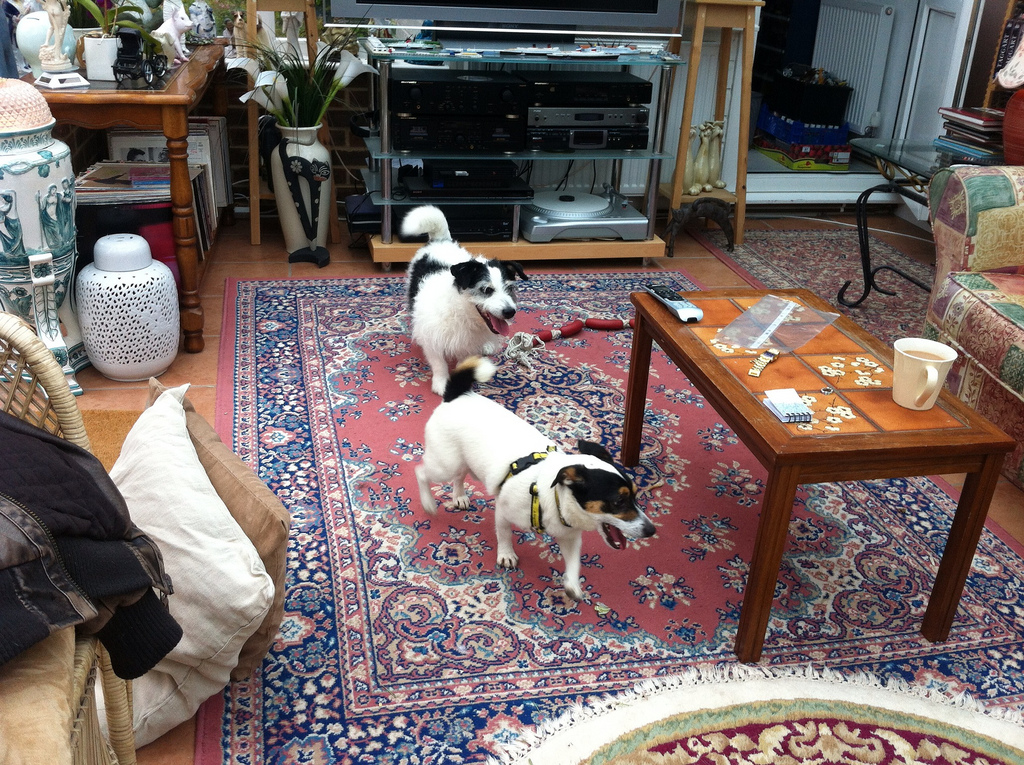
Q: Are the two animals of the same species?
A: Yes, all the animals are dogs.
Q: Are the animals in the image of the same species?
A: Yes, all the animals are dogs.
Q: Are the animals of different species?
A: No, all the animals are dogs.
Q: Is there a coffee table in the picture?
A: Yes, there is a coffee table.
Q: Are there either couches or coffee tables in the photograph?
A: Yes, there is a coffee table.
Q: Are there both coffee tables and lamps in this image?
A: No, there is a coffee table but no lamps.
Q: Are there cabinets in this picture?
A: No, there are no cabinets.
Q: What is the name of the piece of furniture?
A: The piece of furniture is a coffee table.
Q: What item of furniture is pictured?
A: The piece of furniture is a coffee table.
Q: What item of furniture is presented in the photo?
A: The piece of furniture is a coffee table.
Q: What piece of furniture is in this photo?
A: The piece of furniture is a coffee table.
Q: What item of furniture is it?
A: The piece of furniture is a coffee table.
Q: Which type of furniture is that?
A: That is a coffee table.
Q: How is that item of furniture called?
A: That is a coffee table.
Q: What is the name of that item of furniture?
A: That is a coffee table.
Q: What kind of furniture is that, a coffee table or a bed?
A: That is a coffee table.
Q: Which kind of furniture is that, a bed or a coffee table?
A: That is a coffee table.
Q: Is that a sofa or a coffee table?
A: That is a coffee table.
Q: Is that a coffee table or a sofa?
A: That is a coffee table.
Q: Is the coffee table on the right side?
A: Yes, the coffee table is on the right of the image.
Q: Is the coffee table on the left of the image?
A: No, the coffee table is on the right of the image.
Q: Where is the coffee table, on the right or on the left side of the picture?
A: The coffee table is on the right of the image.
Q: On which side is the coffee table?
A: The coffee table is on the right of the image.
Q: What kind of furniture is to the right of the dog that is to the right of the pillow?
A: The piece of furniture is a coffee table.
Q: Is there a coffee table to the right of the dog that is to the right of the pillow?
A: Yes, there is a coffee table to the right of the dog.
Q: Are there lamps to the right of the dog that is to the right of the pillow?
A: No, there is a coffee table to the right of the dog.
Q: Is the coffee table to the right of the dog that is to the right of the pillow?
A: Yes, the coffee table is to the right of the dog.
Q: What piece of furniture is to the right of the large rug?
A: The piece of furniture is a coffee table.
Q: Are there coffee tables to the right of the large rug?
A: Yes, there is a coffee table to the right of the rug.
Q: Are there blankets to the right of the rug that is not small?
A: No, there is a coffee table to the right of the rug.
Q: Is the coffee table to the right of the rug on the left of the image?
A: Yes, the coffee table is to the right of the rug.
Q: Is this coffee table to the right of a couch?
A: No, the coffee table is to the right of the rug.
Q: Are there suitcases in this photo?
A: No, there are no suitcases.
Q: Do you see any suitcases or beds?
A: No, there are no suitcases or beds.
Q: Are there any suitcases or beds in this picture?
A: No, there are no suitcases or beds.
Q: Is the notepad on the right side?
A: Yes, the notepad is on the right of the image.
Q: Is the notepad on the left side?
A: No, the notepad is on the right of the image.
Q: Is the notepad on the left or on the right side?
A: The notepad is on the right of the image.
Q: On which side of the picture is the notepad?
A: The notepad is on the right of the image.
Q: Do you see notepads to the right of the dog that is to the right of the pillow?
A: Yes, there is a notepad to the right of the dog.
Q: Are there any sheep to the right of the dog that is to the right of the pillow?
A: No, there is a notepad to the right of the dog.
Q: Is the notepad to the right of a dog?
A: Yes, the notepad is to the right of a dog.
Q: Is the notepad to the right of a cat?
A: No, the notepad is to the right of a dog.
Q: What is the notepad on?
A: The notepad is on the coffee table.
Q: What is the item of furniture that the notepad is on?
A: The piece of furniture is a coffee table.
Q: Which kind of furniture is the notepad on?
A: The notepad is on the coffee table.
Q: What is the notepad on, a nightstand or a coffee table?
A: The notepad is on a coffee table.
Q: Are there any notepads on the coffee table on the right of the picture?
A: Yes, there is a notepad on the coffee table.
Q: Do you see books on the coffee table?
A: No, there is a notepad on the coffee table.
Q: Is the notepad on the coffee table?
A: Yes, the notepad is on the coffee table.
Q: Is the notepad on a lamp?
A: No, the notepad is on the coffee table.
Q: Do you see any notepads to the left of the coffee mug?
A: Yes, there is a notepad to the left of the coffee mug.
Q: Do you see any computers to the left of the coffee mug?
A: No, there is a notepad to the left of the coffee mug.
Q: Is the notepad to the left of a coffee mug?
A: Yes, the notepad is to the left of a coffee mug.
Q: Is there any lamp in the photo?
A: No, there are no lamps.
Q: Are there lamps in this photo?
A: No, there are no lamps.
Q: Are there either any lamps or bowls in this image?
A: No, there are no lamps or bowls.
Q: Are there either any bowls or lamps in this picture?
A: No, there are no lamps or bowls.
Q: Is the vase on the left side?
A: Yes, the vase is on the left of the image.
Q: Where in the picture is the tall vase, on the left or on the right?
A: The vase is on the left of the image.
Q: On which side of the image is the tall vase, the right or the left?
A: The vase is on the left of the image.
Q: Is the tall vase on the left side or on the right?
A: The vase is on the left of the image.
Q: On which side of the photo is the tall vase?
A: The vase is on the left of the image.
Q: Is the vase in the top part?
A: Yes, the vase is in the top of the image.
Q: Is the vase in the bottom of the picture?
A: No, the vase is in the top of the image.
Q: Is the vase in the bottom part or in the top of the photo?
A: The vase is in the top of the image.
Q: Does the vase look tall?
A: Yes, the vase is tall.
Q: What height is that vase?
A: The vase is tall.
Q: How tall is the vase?
A: The vase is tall.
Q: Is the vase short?
A: No, the vase is tall.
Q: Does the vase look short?
A: No, the vase is tall.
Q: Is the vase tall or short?
A: The vase is tall.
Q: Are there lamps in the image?
A: No, there are no lamps.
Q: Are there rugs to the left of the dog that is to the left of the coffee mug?
A: Yes, there is a rug to the left of the dog.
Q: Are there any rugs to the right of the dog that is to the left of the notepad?
A: No, the rug is to the left of the dog.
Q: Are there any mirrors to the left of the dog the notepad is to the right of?
A: No, there is a rug to the left of the dog.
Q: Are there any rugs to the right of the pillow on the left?
A: Yes, there is a rug to the right of the pillow.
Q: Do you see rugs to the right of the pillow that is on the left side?
A: Yes, there is a rug to the right of the pillow.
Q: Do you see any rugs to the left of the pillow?
A: No, the rug is to the right of the pillow.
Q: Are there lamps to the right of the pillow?
A: No, there is a rug to the right of the pillow.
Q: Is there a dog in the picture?
A: Yes, there is a dog.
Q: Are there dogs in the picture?
A: Yes, there is a dog.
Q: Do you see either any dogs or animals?
A: Yes, there is a dog.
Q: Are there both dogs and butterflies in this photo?
A: No, there is a dog but no butterflies.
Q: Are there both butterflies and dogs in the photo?
A: No, there is a dog but no butterflies.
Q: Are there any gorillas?
A: No, there are no gorillas.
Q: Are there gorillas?
A: No, there are no gorillas.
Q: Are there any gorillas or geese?
A: No, there are no gorillas or geese.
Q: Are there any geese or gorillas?
A: No, there are no gorillas or geese.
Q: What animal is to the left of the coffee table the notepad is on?
A: The animal is a dog.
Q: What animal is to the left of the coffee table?
A: The animal is a dog.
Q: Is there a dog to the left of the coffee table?
A: Yes, there is a dog to the left of the coffee table.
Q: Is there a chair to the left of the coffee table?
A: No, there is a dog to the left of the coffee table.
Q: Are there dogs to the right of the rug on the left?
A: Yes, there is a dog to the right of the rug.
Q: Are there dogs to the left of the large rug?
A: No, the dog is to the right of the rug.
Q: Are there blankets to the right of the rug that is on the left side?
A: No, there is a dog to the right of the rug.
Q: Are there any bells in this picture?
A: No, there are no bells.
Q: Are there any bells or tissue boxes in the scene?
A: No, there are no bells or tissue boxes.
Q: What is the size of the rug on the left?
A: The rug is large.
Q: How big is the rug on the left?
A: The rug is large.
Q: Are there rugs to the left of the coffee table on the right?
A: Yes, there is a rug to the left of the coffee table.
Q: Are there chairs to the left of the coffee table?
A: No, there is a rug to the left of the coffee table.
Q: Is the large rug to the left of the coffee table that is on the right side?
A: Yes, the rug is to the left of the coffee table.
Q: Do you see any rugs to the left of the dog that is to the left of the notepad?
A: Yes, there is a rug to the left of the dog.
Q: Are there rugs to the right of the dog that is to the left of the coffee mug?
A: No, the rug is to the left of the dog.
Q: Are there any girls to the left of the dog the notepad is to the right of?
A: No, there is a rug to the left of the dog.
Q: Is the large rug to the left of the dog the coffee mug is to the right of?
A: Yes, the rug is to the left of the dog.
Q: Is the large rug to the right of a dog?
A: No, the rug is to the left of a dog.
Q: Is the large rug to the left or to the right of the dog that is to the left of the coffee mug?
A: The rug is to the left of the dog.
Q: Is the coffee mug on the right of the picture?
A: Yes, the coffee mug is on the right of the image.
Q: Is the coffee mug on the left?
A: No, the coffee mug is on the right of the image.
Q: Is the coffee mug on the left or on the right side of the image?
A: The coffee mug is on the right of the image.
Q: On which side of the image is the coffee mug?
A: The coffee mug is on the right of the image.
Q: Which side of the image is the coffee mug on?
A: The coffee mug is on the right of the image.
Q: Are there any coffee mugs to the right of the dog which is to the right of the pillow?
A: Yes, there is a coffee mug to the right of the dog.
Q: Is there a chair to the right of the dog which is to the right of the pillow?
A: No, there is a coffee mug to the right of the dog.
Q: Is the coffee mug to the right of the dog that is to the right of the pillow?
A: Yes, the coffee mug is to the right of the dog.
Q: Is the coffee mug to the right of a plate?
A: No, the coffee mug is to the right of the dog.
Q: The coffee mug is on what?
A: The coffee mug is on the coffee table.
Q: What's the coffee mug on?
A: The coffee mug is on the coffee table.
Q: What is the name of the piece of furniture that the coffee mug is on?
A: The piece of furniture is a coffee table.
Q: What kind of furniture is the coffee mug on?
A: The coffee mug is on the coffee table.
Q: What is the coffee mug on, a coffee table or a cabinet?
A: The coffee mug is on a coffee table.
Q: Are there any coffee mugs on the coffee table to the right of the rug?
A: Yes, there is a coffee mug on the coffee table.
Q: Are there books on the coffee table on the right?
A: No, there is a coffee mug on the coffee table.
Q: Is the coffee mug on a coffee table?
A: Yes, the coffee mug is on a coffee table.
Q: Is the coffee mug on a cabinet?
A: No, the coffee mug is on a coffee table.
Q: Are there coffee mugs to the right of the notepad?
A: Yes, there is a coffee mug to the right of the notepad.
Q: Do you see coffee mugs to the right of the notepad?
A: Yes, there is a coffee mug to the right of the notepad.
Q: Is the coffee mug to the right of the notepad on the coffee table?
A: Yes, the coffee mug is to the right of the notepad.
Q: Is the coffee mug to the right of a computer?
A: No, the coffee mug is to the right of the notepad.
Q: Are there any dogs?
A: Yes, there is a dog.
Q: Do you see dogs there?
A: Yes, there is a dog.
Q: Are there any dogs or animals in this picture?
A: Yes, there is a dog.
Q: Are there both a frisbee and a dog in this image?
A: No, there is a dog but no frisbees.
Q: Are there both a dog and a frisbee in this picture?
A: No, there is a dog but no frisbees.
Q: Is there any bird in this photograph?
A: No, there are no birds.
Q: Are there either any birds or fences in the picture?
A: No, there are no birds or fences.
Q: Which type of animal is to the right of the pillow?
A: The animal is a dog.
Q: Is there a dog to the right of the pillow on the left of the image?
A: Yes, there is a dog to the right of the pillow.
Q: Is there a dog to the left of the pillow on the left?
A: No, the dog is to the right of the pillow.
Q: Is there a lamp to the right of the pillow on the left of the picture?
A: No, there is a dog to the right of the pillow.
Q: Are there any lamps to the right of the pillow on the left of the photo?
A: No, there is a dog to the right of the pillow.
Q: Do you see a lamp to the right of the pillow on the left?
A: No, there is a dog to the right of the pillow.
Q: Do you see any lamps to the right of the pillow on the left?
A: No, there is a dog to the right of the pillow.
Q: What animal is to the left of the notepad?
A: The animal is a dog.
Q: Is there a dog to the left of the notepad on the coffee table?
A: Yes, there is a dog to the left of the notepad.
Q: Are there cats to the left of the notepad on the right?
A: No, there is a dog to the left of the notepad.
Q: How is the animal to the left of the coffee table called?
A: The animal is a dog.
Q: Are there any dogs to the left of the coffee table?
A: Yes, there is a dog to the left of the coffee table.